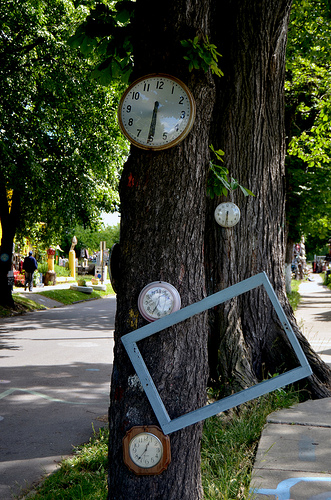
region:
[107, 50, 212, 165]
Clock attached to a tree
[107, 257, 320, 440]
a picture frame attached to a tree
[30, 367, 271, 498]
the grass is green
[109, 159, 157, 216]
a red spot on the tree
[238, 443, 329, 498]
blue drawing on the sidewalk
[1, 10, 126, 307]
tree leaves are green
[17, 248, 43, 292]
A man wearing blue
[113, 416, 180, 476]
The clock is brown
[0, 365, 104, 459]
there is writing on the road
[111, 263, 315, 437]
the picture frame is blue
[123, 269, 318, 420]
A blue frame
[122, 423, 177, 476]
wood clock says its 12:37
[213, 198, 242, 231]
a small clock says its 6:30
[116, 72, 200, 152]
a big clock on the tree says its 6:31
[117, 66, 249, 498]
clocks and picture frame attached to tree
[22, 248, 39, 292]
man with a blue hat on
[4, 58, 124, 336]
a large shade tree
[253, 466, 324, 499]
blue chalk on the sidewalk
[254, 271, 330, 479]
a long sidewalk with some shade in areas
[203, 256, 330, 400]
a large tree trunk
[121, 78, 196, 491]
A tree trunk with 3 clocks and a frame attached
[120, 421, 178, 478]
A wooden clock on a tree trunk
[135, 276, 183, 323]
A pink clock on a tree trunk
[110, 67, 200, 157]
A clock that reads 6:30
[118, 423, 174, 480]
A clock that reads 1:37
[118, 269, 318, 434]
A blue frame on a tree trunk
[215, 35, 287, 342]
A tree trunk with one clock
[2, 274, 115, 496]
A tree shaded street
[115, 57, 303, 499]
Four clocks a frame on two tree trunks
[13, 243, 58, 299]
A man walking on a sidewalk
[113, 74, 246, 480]
There are clocks on the trees.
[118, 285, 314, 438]
The frame is blue.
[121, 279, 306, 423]
The frame is attached to the tree.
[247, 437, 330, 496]
There is blue paint on the sidewalk.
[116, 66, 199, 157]
The highest clock is the largest.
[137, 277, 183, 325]
One clock is pink.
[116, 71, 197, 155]
The large clock says 6:30.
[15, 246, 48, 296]
A man walks on the sidewalk.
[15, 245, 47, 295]
The man wears a jacket and cap.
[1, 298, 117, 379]
There is sun on the sidewalk.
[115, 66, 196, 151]
Large white faced clock on tree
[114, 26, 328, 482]
Two trees close together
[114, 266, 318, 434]
Large blue wooden frame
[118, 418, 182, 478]
clock at the bottom of the tree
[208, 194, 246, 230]
Smallest clock in the background tree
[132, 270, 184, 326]
clock with beige trim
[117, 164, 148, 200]
red mark on the tree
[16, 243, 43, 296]
person walking in the background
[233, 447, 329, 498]
Sidewalk with blue markings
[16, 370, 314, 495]
grass between the trees